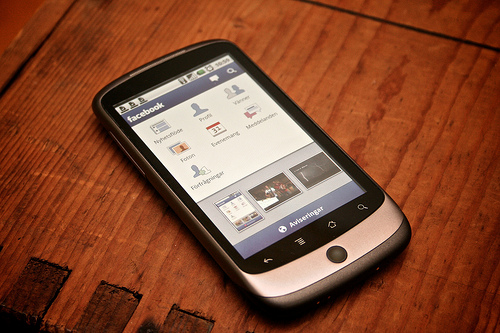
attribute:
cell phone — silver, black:
[81, 31, 433, 331]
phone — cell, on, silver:
[84, 29, 427, 330]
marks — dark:
[1, 245, 217, 330]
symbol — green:
[188, 62, 213, 80]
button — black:
[321, 240, 353, 269]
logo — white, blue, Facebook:
[126, 96, 171, 126]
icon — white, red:
[202, 113, 227, 140]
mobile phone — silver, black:
[82, 27, 422, 325]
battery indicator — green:
[195, 68, 208, 74]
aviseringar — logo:
[290, 204, 322, 228]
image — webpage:
[111, 54, 364, 258]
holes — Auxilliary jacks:
[308, 290, 331, 307]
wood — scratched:
[0, 1, 499, 331]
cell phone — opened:
[88, 31, 420, 316]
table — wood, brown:
[0, 0, 499, 331]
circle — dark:
[324, 242, 349, 267]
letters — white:
[124, 99, 165, 123]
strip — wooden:
[17, 239, 135, 330]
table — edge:
[45, 165, 183, 319]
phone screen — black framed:
[81, 28, 413, 308]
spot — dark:
[31, 2, 121, 95]